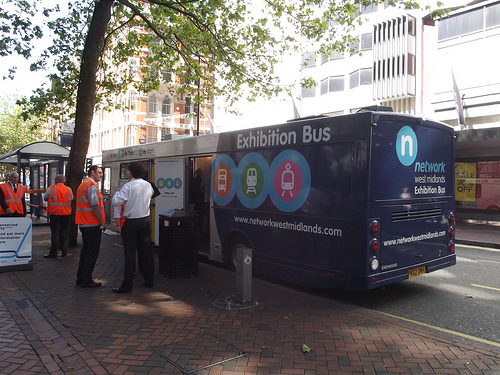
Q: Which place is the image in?
A: It is at the sidewalk.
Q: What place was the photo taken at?
A: It was taken at the sidewalk.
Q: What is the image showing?
A: It is showing a sidewalk.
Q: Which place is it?
A: It is a sidewalk.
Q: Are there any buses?
A: Yes, there is a bus.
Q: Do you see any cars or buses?
A: Yes, there is a bus.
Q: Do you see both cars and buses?
A: No, there is a bus but no cars.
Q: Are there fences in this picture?
A: No, there are no fences.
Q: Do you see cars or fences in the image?
A: No, there are no fences or cars.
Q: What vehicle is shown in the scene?
A: The vehicle is a bus.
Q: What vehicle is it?
A: The vehicle is a bus.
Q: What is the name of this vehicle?
A: This is a bus.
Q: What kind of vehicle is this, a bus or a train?
A: This is a bus.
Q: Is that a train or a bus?
A: That is a bus.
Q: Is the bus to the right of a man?
A: Yes, the bus is to the right of a man.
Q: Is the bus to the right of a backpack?
A: No, the bus is to the right of a man.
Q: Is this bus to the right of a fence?
A: No, the bus is to the right of a safety jacket.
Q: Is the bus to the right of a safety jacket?
A: Yes, the bus is to the right of a safety jacket.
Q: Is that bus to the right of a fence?
A: No, the bus is to the right of a safety jacket.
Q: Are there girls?
A: No, there are no girls.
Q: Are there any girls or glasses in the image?
A: No, there are no girls or glasses.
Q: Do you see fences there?
A: No, there are no fences.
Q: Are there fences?
A: No, there are no fences.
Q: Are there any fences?
A: No, there are no fences.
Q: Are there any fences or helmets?
A: No, there are no fences or helmets.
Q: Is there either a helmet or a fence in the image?
A: No, there are no fences or helmets.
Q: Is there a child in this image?
A: No, there are no children.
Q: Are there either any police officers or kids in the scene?
A: No, there are no kids or police officers.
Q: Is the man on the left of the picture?
A: Yes, the man is on the left of the image.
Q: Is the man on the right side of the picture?
A: No, the man is on the left of the image.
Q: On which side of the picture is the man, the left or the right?
A: The man is on the left of the image.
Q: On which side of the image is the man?
A: The man is on the left of the image.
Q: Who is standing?
A: The man is standing.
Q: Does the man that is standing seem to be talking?
A: Yes, the man is talking.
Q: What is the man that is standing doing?
A: The man is talking.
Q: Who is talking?
A: The man is talking.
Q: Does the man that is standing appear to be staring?
A: No, the man is talking.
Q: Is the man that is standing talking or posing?
A: The man is talking.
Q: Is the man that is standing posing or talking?
A: The man is talking.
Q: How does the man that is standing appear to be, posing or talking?
A: The man is talking.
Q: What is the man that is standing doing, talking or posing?
A: The man is talking.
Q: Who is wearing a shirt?
A: The man is wearing a shirt.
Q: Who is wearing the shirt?
A: The man is wearing a shirt.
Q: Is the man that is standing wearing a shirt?
A: Yes, the man is wearing a shirt.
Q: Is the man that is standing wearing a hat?
A: No, the man is wearing a shirt.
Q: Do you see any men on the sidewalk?
A: Yes, there is a man on the sidewalk.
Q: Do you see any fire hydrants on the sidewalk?
A: No, there is a man on the sidewalk.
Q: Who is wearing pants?
A: The man is wearing pants.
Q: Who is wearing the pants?
A: The man is wearing pants.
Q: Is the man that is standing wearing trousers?
A: Yes, the man is wearing trousers.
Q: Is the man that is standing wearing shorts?
A: No, the man is wearing trousers.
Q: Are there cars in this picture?
A: No, there are no cars.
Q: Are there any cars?
A: No, there are no cars.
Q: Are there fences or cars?
A: No, there are no cars or fences.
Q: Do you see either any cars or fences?
A: No, there are no cars or fences.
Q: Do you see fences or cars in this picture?
A: No, there are no cars or fences.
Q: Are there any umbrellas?
A: No, there are no umbrellas.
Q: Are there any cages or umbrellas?
A: No, there are no umbrellas or cages.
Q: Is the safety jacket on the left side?
A: Yes, the safety jacket is on the left of the image.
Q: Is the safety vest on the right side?
A: No, the safety vest is on the left of the image.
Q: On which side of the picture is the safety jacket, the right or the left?
A: The safety jacket is on the left of the image.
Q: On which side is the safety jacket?
A: The safety jacket is on the left of the image.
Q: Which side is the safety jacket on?
A: The safety jacket is on the left of the image.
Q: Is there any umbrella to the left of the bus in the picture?
A: No, there is a safety jacket to the left of the bus.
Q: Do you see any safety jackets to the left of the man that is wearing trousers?
A: Yes, there is a safety jacket to the left of the man.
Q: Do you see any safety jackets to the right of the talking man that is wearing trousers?
A: No, the safety jacket is to the left of the man.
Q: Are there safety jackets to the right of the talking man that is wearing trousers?
A: No, the safety jacket is to the left of the man.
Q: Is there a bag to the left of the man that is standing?
A: No, there is a safety jacket to the left of the man.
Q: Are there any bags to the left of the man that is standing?
A: No, there is a safety jacket to the left of the man.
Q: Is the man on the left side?
A: Yes, the man is on the left of the image.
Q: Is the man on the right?
A: No, the man is on the left of the image.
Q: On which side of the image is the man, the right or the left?
A: The man is on the left of the image.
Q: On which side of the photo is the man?
A: The man is on the left of the image.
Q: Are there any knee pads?
A: No, there are no knee pads.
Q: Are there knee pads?
A: No, there are no knee pads.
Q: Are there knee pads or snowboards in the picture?
A: No, there are no knee pads or snowboards.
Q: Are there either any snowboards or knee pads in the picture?
A: No, there are no knee pads or snowboards.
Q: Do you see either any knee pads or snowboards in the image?
A: No, there are no knee pads or snowboards.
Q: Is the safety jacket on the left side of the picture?
A: Yes, the safety jacket is on the left of the image.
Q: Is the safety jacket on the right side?
A: No, the safety jacket is on the left of the image.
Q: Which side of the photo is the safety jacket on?
A: The safety jacket is on the left of the image.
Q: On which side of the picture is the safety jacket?
A: The safety jacket is on the left of the image.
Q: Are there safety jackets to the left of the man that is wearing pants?
A: Yes, there is a safety jacket to the left of the man.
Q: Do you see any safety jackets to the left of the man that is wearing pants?
A: Yes, there is a safety jacket to the left of the man.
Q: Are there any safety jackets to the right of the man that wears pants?
A: No, the safety jacket is to the left of the man.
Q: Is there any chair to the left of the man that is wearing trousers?
A: No, there is a safety jacket to the left of the man.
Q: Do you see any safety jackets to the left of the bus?
A: Yes, there is a safety jacket to the left of the bus.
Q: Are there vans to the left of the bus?
A: No, there is a safety jacket to the left of the bus.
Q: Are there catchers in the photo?
A: No, there are no catchers.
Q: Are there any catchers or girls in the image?
A: No, there are no catchers or girls.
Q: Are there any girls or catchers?
A: No, there are no catchers or girls.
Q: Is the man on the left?
A: Yes, the man is on the left of the image.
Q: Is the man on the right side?
A: No, the man is on the left of the image.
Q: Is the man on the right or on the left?
A: The man is on the left of the image.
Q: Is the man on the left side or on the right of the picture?
A: The man is on the left of the image.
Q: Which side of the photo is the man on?
A: The man is on the left of the image.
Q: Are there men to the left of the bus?
A: Yes, there is a man to the left of the bus.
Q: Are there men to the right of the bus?
A: No, the man is to the left of the bus.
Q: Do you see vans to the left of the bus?
A: No, there is a man to the left of the bus.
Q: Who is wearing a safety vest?
A: The man is wearing a safety vest.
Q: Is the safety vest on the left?
A: Yes, the safety vest is on the left of the image.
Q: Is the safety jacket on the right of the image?
A: No, the safety jacket is on the left of the image.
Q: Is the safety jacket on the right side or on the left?
A: The safety jacket is on the left of the image.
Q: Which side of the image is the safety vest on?
A: The safety vest is on the left of the image.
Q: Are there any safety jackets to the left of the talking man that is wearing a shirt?
A: Yes, there is a safety jacket to the left of the man.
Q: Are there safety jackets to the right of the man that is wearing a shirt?
A: No, the safety jacket is to the left of the man.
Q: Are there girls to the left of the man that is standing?
A: No, there is a safety jacket to the left of the man.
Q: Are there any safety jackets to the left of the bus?
A: Yes, there is a safety jacket to the left of the bus.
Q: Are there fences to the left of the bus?
A: No, there is a safety jacket to the left of the bus.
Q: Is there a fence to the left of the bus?
A: No, there is a safety jacket to the left of the bus.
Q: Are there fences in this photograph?
A: No, there are no fences.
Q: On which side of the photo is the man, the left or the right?
A: The man is on the left of the image.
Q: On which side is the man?
A: The man is on the left of the image.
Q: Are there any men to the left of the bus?
A: Yes, there is a man to the left of the bus.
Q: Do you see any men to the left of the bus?
A: Yes, there is a man to the left of the bus.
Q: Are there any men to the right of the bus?
A: No, the man is to the left of the bus.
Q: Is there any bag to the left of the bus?
A: No, there is a man to the left of the bus.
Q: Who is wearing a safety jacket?
A: The man is wearing a safety jacket.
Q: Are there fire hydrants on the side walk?
A: No, there is a man on the side walk.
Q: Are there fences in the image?
A: No, there are no fences.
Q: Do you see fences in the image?
A: No, there are no fences.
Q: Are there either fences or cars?
A: No, there are no fences or cars.